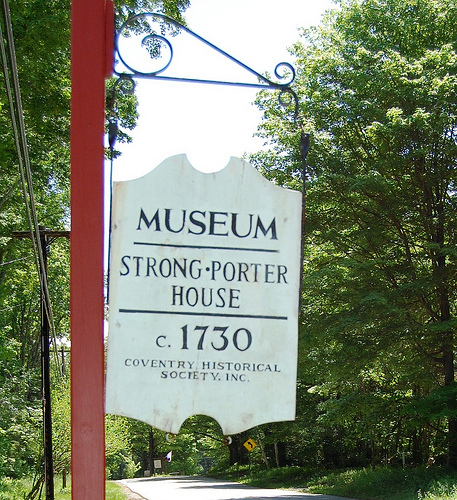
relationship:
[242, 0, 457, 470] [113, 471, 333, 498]
clump trees standing alongside road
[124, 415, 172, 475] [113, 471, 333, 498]
tree standing alongside road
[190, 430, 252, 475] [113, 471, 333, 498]
tree standing alongside road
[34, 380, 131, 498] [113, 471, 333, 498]
tree standing alongside road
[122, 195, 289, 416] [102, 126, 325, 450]
writing on sign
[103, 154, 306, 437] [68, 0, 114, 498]
sign attached to post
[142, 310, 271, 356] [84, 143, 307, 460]
year on sign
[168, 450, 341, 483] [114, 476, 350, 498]
grass next to road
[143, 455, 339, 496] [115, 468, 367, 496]
shadow on ground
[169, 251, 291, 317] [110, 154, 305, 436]
porter house on sign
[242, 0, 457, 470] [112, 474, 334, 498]
clump trees on side of road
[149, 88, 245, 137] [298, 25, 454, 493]
sky between trees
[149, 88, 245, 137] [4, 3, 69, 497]
sky between trees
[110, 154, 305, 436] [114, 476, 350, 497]
sign next to road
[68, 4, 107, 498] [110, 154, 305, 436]
post holding sign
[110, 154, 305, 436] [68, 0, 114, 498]
sign hanging on post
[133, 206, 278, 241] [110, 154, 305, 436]
words are on sign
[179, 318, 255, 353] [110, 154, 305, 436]
1730 on sign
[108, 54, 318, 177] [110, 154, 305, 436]
metal on sign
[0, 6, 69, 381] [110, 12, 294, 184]
power line in sky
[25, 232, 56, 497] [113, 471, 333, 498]
pole next to road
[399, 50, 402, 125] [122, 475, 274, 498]
clump trees by road